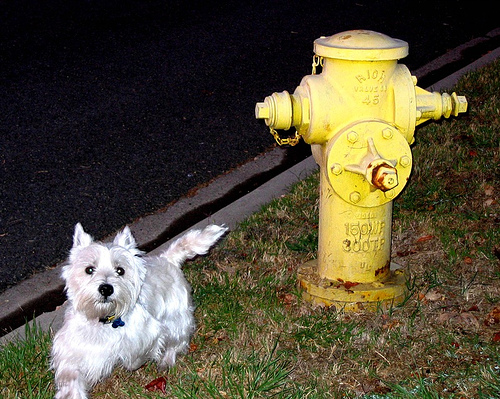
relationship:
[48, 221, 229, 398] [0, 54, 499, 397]
dog on grass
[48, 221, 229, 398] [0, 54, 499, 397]
dog laying on grass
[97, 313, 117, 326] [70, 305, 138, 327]
collar around neck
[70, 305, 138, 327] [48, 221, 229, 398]
neck of dog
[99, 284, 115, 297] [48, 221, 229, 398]
nose of dog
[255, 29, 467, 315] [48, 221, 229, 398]
fire hydrant next to dog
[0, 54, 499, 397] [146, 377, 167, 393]
grass with leaf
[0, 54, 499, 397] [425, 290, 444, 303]
grass with leaf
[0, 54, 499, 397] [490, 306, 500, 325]
grass with leaf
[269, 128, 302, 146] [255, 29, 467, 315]
chain on fire hydrant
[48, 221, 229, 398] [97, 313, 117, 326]
dog with collar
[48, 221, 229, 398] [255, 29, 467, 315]
dog and fire hydrant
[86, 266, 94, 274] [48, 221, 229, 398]
eye of dog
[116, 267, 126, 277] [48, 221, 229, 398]
eye of dog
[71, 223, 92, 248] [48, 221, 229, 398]
ear of dog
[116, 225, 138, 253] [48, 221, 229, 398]
ear of dog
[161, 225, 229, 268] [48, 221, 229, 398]
tail of dog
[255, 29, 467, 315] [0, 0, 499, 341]
fire hydrant on road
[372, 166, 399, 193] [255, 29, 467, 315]
nut on fire hydrant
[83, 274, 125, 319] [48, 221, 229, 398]
muzzle of dog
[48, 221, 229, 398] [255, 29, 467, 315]
dog near fire hydrant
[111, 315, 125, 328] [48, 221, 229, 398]
name tag on dog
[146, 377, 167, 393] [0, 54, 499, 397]
leaf in grass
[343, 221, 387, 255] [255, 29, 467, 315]
lettering on fire hydrant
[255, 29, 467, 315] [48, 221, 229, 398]
fire hydrant near dog